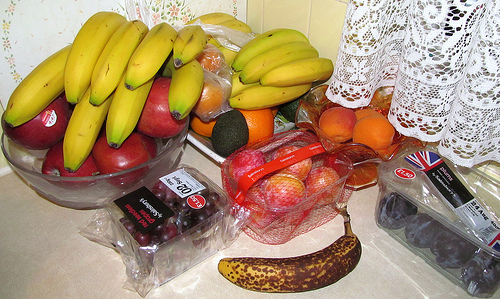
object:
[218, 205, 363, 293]
banana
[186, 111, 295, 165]
dish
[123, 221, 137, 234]
grapes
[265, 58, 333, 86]
banana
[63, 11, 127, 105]
banana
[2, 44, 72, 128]
banana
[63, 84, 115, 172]
banana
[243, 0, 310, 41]
tile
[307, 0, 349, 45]
tile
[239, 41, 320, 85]
banana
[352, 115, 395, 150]
apricots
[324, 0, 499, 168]
curatin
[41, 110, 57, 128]
sticker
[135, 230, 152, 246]
grapes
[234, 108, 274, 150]
orange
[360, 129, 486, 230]
union jack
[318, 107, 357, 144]
peaches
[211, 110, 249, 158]
avocado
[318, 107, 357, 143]
peach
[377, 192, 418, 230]
plum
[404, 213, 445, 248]
plum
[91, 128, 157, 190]
apple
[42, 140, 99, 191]
apple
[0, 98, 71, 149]
apple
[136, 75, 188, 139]
apple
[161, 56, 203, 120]
banana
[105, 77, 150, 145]
banana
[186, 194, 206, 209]
sticker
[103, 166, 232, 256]
plastic box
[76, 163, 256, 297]
box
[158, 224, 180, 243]
grape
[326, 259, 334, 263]
brown parts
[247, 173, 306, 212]
nectarines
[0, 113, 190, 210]
bowl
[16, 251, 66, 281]
table.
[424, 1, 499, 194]
window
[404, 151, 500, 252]
sticker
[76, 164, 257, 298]
package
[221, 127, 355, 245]
package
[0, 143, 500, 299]
counter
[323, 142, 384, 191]
bowl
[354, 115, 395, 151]
peach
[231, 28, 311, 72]
banana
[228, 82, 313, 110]
banana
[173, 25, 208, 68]
banana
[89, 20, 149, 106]
banana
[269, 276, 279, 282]
brown spots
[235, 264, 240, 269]
brown spots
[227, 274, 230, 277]
brown spots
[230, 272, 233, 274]
brown spots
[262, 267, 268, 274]
brown spots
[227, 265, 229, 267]
brown spots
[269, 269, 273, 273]
brown spots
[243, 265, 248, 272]
brown spots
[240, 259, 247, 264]
brown spots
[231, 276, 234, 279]
brown spots